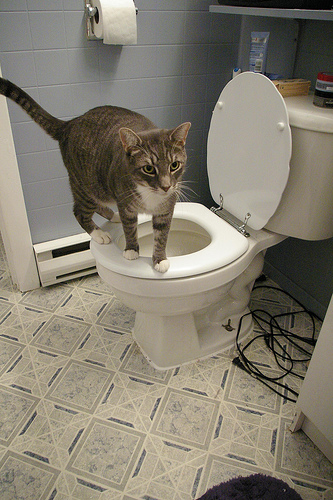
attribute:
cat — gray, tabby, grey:
[1, 80, 196, 273]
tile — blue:
[54, 399, 166, 498]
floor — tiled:
[0, 245, 332, 499]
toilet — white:
[91, 73, 331, 372]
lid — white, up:
[204, 71, 292, 233]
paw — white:
[154, 254, 168, 272]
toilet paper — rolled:
[88, 2, 140, 47]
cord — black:
[233, 282, 316, 404]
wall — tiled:
[2, 1, 239, 248]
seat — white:
[92, 201, 248, 279]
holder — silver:
[85, 4, 138, 18]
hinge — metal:
[237, 212, 253, 236]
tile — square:
[34, 49, 79, 88]